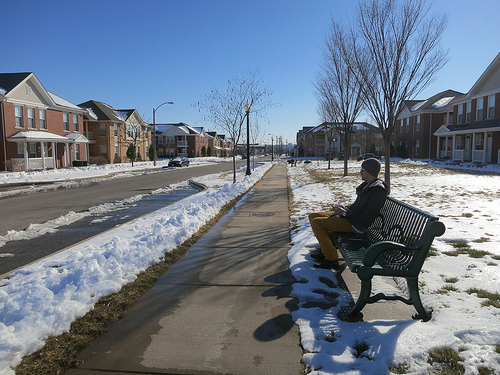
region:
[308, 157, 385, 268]
The man sittin on the bench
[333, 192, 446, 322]
The bench being sat on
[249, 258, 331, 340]
The man's shadow on the ground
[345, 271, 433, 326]
The near legs of the bench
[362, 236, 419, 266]
The near armrest of the bench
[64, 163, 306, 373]
The sidewalk in front of the man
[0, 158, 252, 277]
The street that has been plowed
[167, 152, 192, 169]
The car parked at the curb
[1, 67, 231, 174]
The houses on the opposite side of the street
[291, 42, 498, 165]
Houses behind the sitting man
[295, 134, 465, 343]
man sitting on green bench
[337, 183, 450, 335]
bench is made of metal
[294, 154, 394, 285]
man is wearing brown pants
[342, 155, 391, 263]
man is wearing black jacket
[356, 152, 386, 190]
man wearing black hat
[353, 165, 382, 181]
man wearing black sunglasses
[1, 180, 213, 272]
icy patch on street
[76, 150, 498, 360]
grass showing through snow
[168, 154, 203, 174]
black car parked on street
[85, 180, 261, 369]
wet pavement on sidewalk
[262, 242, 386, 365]
A black shadow on the snowy ground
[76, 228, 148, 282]
Thick white snow on the ground by the road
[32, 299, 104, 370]
Short green grass by the sidewalk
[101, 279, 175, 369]
Water seeping along the sidewalk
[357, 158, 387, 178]
A grey hat on the mans's head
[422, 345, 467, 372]
Sparse green grass growing through the snow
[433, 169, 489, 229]
Thin white snow fallen on the ground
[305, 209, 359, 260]
Brown pants on the sitting man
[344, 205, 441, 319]
A black bench under the sitting man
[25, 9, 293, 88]
The sky is clear and blue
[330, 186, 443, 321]
green bench to the right of a sidewalk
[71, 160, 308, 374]
long straight sidewalk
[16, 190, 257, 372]
grass next to sidewalk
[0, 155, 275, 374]
snow next to grass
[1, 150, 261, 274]
street to the left of sidewalk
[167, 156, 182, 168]
car parked on top of the street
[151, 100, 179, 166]
lamp post next to street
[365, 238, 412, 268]
the bench has an arm rest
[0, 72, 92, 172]
brick house to the left of street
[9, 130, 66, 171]
porch on house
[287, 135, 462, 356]
a man on a bench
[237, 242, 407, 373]
shadow on the ground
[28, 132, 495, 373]
snow covers most of the ground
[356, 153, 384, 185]
gray hat on head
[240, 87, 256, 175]
a black lamp post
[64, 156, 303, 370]
the sidewalk is cleared of snow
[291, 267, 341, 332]
foot prints in the snow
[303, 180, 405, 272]
black jacket and brown pants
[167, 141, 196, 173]
a black car parked at the curb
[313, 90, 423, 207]
trees with no leaves